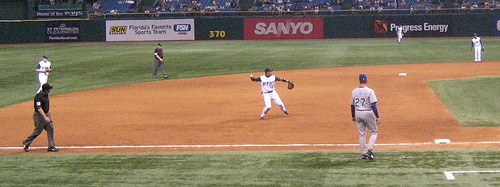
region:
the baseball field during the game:
[10, 40, 499, 185]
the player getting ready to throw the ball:
[243, 64, 296, 119]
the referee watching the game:
[22, 82, 59, 157]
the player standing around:
[461, 31, 482, 59]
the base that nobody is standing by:
[432, 135, 451, 146]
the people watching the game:
[103, 0, 498, 12]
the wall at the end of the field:
[6, 16, 498, 35]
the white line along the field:
[3, 125, 497, 152]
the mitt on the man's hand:
[287, 80, 297, 90]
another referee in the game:
[150, 42, 164, 74]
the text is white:
[243, 7, 331, 48]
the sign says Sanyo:
[251, 14, 326, 42]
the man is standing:
[347, 67, 387, 164]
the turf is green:
[167, 157, 279, 183]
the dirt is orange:
[129, 91, 231, 126]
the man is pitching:
[249, 54, 302, 125]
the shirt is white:
[343, 83, 381, 111]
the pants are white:
[348, 112, 391, 156]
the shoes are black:
[358, 145, 380, 164]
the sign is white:
[104, 11, 202, 53]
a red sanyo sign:
[245, 9, 363, 57]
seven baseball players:
[22, 12, 497, 157]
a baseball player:
[244, 55, 330, 147]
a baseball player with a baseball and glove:
[236, 55, 311, 127]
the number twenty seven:
[336, 62, 401, 171]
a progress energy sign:
[361, 8, 493, 52]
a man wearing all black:
[16, 68, 78, 157]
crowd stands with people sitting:
[91, 0, 464, 42]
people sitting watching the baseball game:
[97, 0, 382, 46]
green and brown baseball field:
[29, 55, 467, 175]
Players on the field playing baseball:
[17, 22, 494, 159]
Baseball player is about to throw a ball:
[235, 61, 314, 131]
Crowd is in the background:
[149, 0, 486, 17]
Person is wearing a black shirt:
[18, 76, 75, 124]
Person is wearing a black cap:
[26, 72, 78, 110]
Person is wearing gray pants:
[13, 103, 73, 158]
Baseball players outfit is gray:
[336, 63, 411, 180]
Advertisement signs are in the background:
[42, 15, 489, 45]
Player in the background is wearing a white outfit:
[31, 48, 62, 85]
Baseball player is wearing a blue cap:
[349, 63, 375, 99]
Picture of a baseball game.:
[21, 9, 496, 171]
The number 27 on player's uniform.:
[346, 91, 379, 113]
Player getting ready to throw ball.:
[244, 51, 300, 120]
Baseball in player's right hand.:
[245, 66, 258, 86]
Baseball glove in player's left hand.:
[280, 76, 300, 92]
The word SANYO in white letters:
[246, 17, 327, 38]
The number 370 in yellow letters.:
[206, 25, 232, 44]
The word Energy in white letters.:
[418, 15, 460, 36]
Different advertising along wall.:
[29, 11, 463, 43]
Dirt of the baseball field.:
[116, 87, 219, 133]